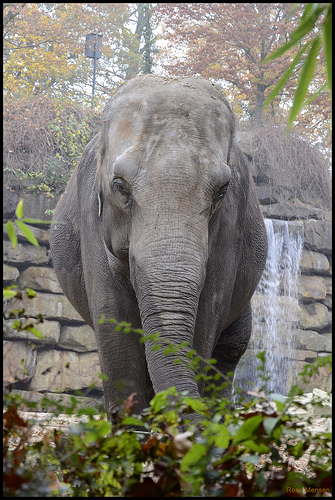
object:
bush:
[21, 392, 329, 492]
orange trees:
[0, 0, 141, 103]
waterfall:
[232, 218, 305, 405]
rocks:
[254, 164, 332, 217]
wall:
[2, 174, 334, 418]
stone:
[4, 240, 49, 267]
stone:
[17, 263, 64, 293]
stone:
[56, 322, 97, 353]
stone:
[278, 244, 329, 274]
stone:
[298, 300, 334, 331]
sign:
[84, 33, 102, 58]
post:
[91, 34, 98, 110]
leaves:
[198, 418, 234, 450]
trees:
[161, 23, 332, 162]